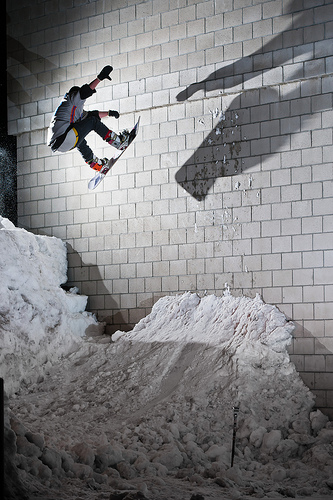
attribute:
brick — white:
[211, 32, 266, 82]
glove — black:
[97, 63, 117, 81]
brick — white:
[88, 267, 103, 281]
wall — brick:
[182, 42, 277, 153]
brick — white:
[298, 318, 330, 348]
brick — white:
[256, 115, 283, 138]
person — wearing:
[44, 65, 130, 174]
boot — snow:
[104, 127, 131, 151]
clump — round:
[93, 440, 125, 467]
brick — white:
[102, 203, 120, 220]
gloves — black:
[96, 63, 123, 120]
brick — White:
[200, 69, 278, 191]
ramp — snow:
[111, 283, 288, 455]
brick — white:
[84, 233, 106, 252]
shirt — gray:
[51, 98, 81, 136]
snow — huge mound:
[61, 311, 217, 440]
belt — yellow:
[67, 123, 91, 157]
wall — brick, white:
[47, 30, 326, 342]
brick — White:
[238, 205, 276, 228]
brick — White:
[158, 101, 194, 126]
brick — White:
[89, 197, 124, 230]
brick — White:
[109, 28, 145, 58]